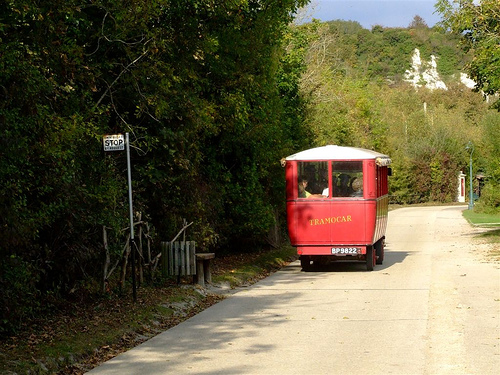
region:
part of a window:
[331, 150, 361, 180]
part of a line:
[331, 308, 358, 339]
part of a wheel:
[362, 251, 374, 271]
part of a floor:
[344, 295, 367, 327]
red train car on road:
[281, 135, 393, 279]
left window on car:
[301, 162, 329, 198]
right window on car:
[331, 163, 367, 196]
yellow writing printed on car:
[311, 211, 356, 230]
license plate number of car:
[333, 246, 359, 254]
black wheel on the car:
[363, 244, 378, 269]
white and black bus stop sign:
[100, 127, 124, 151]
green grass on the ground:
[63, 333, 97, 349]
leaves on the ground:
[27, 332, 48, 347]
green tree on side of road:
[463, 13, 498, 156]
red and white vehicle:
[268, 145, 407, 284]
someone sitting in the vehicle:
[294, 174, 325, 199]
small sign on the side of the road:
[94, 124, 161, 291]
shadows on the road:
[117, 249, 320, 374]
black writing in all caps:
[104, 137, 124, 147]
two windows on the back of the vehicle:
[289, 161, 365, 201]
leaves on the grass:
[12, 288, 153, 365]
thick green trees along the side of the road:
[0, 2, 318, 294]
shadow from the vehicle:
[304, 245, 414, 273]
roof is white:
[278, 138, 383, 161]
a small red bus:
[17, 13, 478, 348]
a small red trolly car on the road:
[88, 96, 491, 312]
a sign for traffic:
[87, 121, 164, 289]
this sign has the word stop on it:
[94, 134, 163, 281]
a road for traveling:
[270, 118, 477, 369]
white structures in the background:
[394, 48, 497, 101]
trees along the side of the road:
[24, 19, 279, 313]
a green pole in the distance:
[452, 134, 485, 215]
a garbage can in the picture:
[159, 235, 225, 294]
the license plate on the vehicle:
[327, 241, 366, 257]